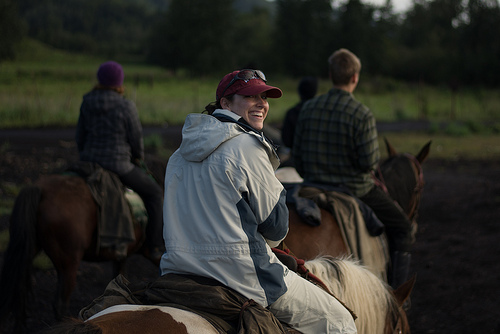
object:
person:
[73, 60, 167, 264]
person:
[280, 75, 320, 158]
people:
[152, 67, 366, 334]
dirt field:
[406, 146, 496, 332]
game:
[0, 45, 500, 334]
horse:
[272, 134, 436, 282]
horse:
[36, 246, 421, 334]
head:
[379, 271, 422, 333]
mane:
[305, 249, 392, 332]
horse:
[4, 158, 166, 331]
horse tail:
[2, 182, 48, 329]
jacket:
[154, 100, 295, 309]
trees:
[458, 0, 498, 88]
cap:
[213, 68, 284, 104]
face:
[234, 85, 273, 131]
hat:
[95, 63, 125, 91]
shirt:
[290, 87, 385, 201]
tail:
[43, 315, 110, 334]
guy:
[290, 48, 419, 296]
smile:
[245, 97, 271, 122]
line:
[212, 150, 286, 215]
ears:
[417, 137, 437, 162]